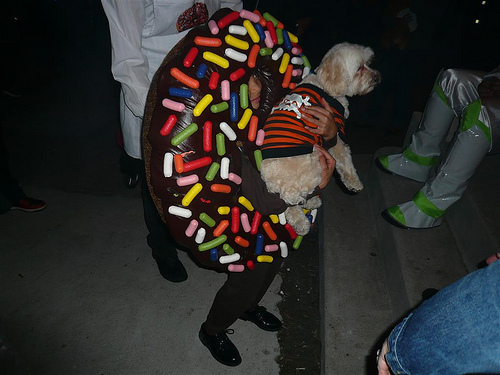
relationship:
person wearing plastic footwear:
[377, 57, 487, 238] [381, 80, 483, 225]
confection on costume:
[182, 44, 195, 67] [139, 7, 318, 273]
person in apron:
[97, 0, 264, 281] [101, 0, 243, 160]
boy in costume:
[199, 73, 338, 367] [135, 7, 323, 275]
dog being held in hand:
[257, 43, 385, 208] [291, 93, 341, 141]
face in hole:
[243, 72, 265, 108] [234, 60, 273, 117]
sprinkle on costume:
[166, 115, 213, 148] [117, 27, 430, 256]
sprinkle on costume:
[214, 75, 236, 105] [139, 7, 329, 365]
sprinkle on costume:
[160, 152, 177, 182] [127, 31, 343, 245]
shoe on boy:
[176, 317, 254, 374] [117, 33, 355, 302]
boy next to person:
[199, 73, 338, 367] [99, 1, 247, 192]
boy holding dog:
[199, 73, 338, 367] [261, 35, 377, 198]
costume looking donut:
[139, 7, 318, 273] [138, 10, 336, 283]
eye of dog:
[355, 62, 367, 74] [258, 44, 377, 231]